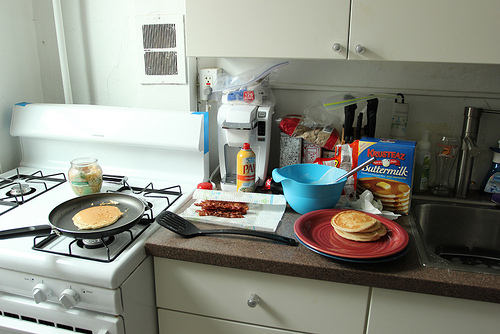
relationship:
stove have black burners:
[3, 103, 202, 332] [0, 172, 189, 262]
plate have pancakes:
[293, 207, 411, 259] [330, 208, 389, 242]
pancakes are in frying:
[71, 204, 122, 231] [0, 191, 146, 251]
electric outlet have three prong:
[198, 69, 217, 97] [207, 78, 210, 83]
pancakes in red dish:
[71, 204, 122, 231] [293, 207, 411, 259]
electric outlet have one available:
[198, 69, 217, 97] [196, 72, 215, 83]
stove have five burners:
[3, 103, 202, 332] [0, 172, 189, 262]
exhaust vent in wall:
[136, 13, 187, 88] [49, 1, 193, 114]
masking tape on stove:
[190, 111, 208, 153] [3, 103, 202, 332]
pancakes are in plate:
[330, 208, 389, 242] [293, 207, 411, 259]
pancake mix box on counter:
[352, 139, 416, 217] [150, 179, 499, 330]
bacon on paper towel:
[193, 201, 250, 218] [171, 188, 289, 230]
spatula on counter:
[156, 210, 299, 239] [150, 179, 499, 330]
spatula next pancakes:
[156, 210, 299, 239] [330, 208, 389, 242]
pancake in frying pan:
[71, 204, 122, 231] [0, 191, 146, 251]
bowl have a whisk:
[272, 163, 347, 217] [337, 154, 378, 186]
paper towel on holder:
[389, 93, 409, 143] [392, 89, 412, 145]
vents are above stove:
[136, 13, 187, 88] [3, 103, 202, 332]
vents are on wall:
[136, 13, 187, 88] [49, 1, 193, 114]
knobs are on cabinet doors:
[330, 41, 368, 58] [182, 1, 499, 64]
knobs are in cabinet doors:
[330, 41, 368, 58] [182, 1, 499, 64]